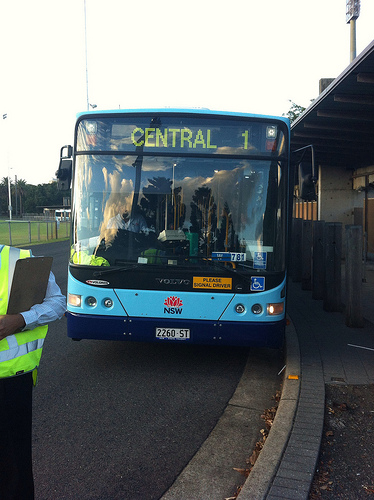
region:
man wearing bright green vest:
[0, 240, 49, 385]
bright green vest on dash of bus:
[69, 245, 108, 269]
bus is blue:
[56, 108, 318, 346]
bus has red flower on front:
[163, 293, 184, 308]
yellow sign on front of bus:
[191, 275, 233, 292]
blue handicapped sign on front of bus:
[249, 274, 264, 291]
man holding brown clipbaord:
[6, 253, 52, 321]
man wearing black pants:
[1, 370, 38, 498]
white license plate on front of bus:
[151, 324, 191, 340]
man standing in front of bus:
[0, 239, 69, 498]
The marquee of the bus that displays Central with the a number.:
[113, 125, 262, 153]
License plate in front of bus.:
[156, 328, 190, 339]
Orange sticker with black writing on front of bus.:
[194, 276, 231, 289]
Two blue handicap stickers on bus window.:
[252, 248, 266, 291]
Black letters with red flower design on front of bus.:
[158, 292, 187, 314]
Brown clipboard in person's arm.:
[7, 255, 53, 312]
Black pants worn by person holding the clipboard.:
[0, 377, 30, 498]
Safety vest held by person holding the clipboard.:
[0, 242, 45, 383]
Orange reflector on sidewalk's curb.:
[288, 370, 299, 383]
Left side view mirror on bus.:
[54, 142, 73, 195]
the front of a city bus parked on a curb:
[49, 98, 300, 350]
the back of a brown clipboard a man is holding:
[6, 256, 52, 323]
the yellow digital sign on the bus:
[126, 121, 259, 160]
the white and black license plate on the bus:
[153, 323, 194, 345]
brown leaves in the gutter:
[254, 385, 288, 475]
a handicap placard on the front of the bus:
[245, 271, 265, 294]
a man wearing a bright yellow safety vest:
[1, 239, 64, 498]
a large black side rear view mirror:
[295, 143, 324, 207]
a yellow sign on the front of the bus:
[193, 276, 233, 292]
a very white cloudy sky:
[133, 72, 264, 109]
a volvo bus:
[57, 100, 295, 359]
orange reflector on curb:
[280, 366, 304, 390]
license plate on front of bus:
[148, 324, 199, 345]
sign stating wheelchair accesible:
[246, 271, 263, 293]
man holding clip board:
[0, 234, 69, 492]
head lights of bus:
[81, 292, 115, 310]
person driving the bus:
[103, 195, 151, 238]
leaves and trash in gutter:
[235, 388, 281, 491]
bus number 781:
[226, 247, 245, 262]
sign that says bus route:
[121, 123, 257, 152]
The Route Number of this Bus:
[103, 120, 261, 152]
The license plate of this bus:
[142, 322, 206, 344]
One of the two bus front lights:
[65, 286, 83, 307]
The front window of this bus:
[74, 154, 276, 272]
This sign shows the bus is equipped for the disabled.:
[248, 274, 268, 290]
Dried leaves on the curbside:
[243, 406, 273, 420]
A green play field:
[10, 221, 29, 242]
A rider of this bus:
[96, 196, 150, 236]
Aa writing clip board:
[2, 248, 54, 320]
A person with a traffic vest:
[6, 232, 38, 439]